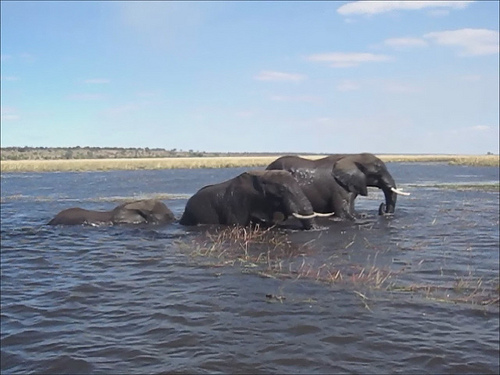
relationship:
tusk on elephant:
[283, 204, 338, 227] [194, 130, 419, 249]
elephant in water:
[182, 173, 335, 233] [1, 163, 500, 373]